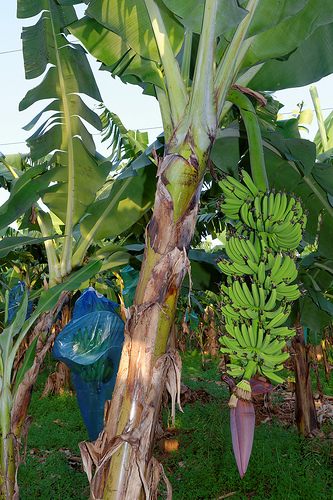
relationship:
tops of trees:
[5, 76, 290, 327] [1, 1, 331, 495]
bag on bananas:
[51, 284, 123, 441] [69, 325, 107, 383]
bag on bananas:
[51, 284, 125, 442] [73, 327, 112, 358]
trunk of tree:
[88, 165, 205, 483] [67, 2, 303, 490]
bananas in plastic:
[51, 309, 124, 440] [50, 287, 123, 443]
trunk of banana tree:
[88, 138, 212, 499] [62, 0, 332, 499]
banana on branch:
[268, 218, 280, 236] [226, 89, 271, 190]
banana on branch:
[244, 209, 255, 229] [226, 89, 271, 190]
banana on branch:
[257, 235, 268, 258] [226, 89, 271, 190]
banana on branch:
[243, 239, 260, 258] [226, 89, 271, 190]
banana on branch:
[254, 262, 266, 285] [226, 89, 271, 190]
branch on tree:
[226, 89, 271, 190] [64, 0, 331, 498]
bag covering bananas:
[51, 284, 125, 442] [221, 273, 290, 319]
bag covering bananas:
[51, 284, 125, 442] [225, 184, 291, 225]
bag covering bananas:
[51, 284, 125, 442] [226, 231, 291, 275]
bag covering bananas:
[51, 284, 125, 442] [66, 323, 115, 379]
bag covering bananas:
[51, 284, 125, 442] [223, 323, 284, 373]